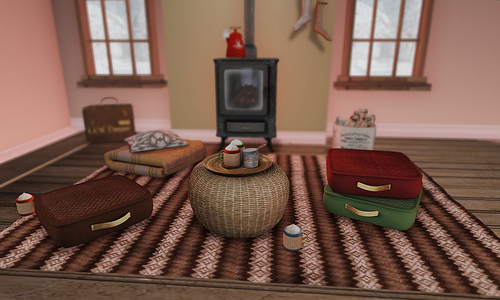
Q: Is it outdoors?
A: Yes, it is outdoors.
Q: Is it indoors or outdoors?
A: It is outdoors.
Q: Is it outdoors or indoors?
A: It is outdoors.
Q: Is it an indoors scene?
A: No, it is outdoors.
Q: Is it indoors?
A: No, it is outdoors.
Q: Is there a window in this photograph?
A: Yes, there is a window.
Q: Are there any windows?
A: Yes, there is a window.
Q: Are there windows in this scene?
A: Yes, there is a window.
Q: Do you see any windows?
A: Yes, there is a window.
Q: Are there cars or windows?
A: Yes, there is a window.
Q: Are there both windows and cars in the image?
A: No, there is a window but no cars.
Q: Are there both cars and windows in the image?
A: No, there is a window but no cars.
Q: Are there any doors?
A: No, there are no doors.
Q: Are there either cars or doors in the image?
A: No, there are no doors or cars.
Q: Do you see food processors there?
A: No, there are no food processors.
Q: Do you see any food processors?
A: No, there are no food processors.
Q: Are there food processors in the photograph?
A: No, there are no food processors.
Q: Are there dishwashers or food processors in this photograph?
A: No, there are no food processors or dishwashers.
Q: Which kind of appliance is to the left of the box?
A: The appliance is a stove.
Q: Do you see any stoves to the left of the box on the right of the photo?
A: Yes, there is a stove to the left of the box.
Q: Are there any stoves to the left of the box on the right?
A: Yes, there is a stove to the left of the box.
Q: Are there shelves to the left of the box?
A: No, there is a stove to the left of the box.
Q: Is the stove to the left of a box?
A: Yes, the stove is to the left of a box.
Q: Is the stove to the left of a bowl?
A: No, the stove is to the left of a box.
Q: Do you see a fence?
A: No, there are no fences.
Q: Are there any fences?
A: No, there are no fences.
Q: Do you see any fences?
A: No, there are no fences.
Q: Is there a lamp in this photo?
A: No, there are no lamps.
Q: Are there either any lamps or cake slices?
A: No, there are no lamps or cake slices.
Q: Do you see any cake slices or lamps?
A: No, there are no lamps or cake slices.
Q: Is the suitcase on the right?
A: No, the suitcase is on the left of the image.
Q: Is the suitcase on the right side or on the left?
A: The suitcase is on the left of the image.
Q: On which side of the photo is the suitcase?
A: The suitcase is on the left of the image.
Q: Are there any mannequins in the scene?
A: No, there are no mannequins.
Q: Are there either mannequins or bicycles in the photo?
A: No, there are no mannequins or bicycles.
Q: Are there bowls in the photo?
A: No, there are no bowls.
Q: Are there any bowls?
A: No, there are no bowls.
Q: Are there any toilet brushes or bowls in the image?
A: No, there are no bowls or toilet brushes.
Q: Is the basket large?
A: Yes, the basket is large.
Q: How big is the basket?
A: The basket is large.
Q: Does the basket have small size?
A: No, the basket is large.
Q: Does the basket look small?
A: No, the basket is large.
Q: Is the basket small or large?
A: The basket is large.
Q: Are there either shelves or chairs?
A: No, there are no chairs or shelves.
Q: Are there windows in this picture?
A: Yes, there is a window.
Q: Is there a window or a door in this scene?
A: Yes, there is a window.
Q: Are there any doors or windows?
A: Yes, there is a window.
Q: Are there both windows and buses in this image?
A: No, there is a window but no buses.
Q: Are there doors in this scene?
A: No, there are no doors.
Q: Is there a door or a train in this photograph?
A: No, there are no doors or trains.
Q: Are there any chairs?
A: No, there are no chairs.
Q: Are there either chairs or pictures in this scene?
A: No, there are no chairs or pictures.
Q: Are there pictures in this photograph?
A: No, there are no pictures.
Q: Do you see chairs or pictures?
A: No, there are no pictures or chairs.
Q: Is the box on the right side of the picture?
A: Yes, the box is on the right of the image.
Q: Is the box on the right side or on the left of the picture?
A: The box is on the right of the image.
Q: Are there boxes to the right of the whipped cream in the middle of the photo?
A: Yes, there is a box to the right of the whipped cream.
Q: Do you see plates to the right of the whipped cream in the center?
A: No, there is a box to the right of the whipped cream.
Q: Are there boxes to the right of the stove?
A: Yes, there is a box to the right of the stove.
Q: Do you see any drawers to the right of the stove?
A: No, there is a box to the right of the stove.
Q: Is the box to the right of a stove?
A: Yes, the box is to the right of a stove.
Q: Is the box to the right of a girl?
A: No, the box is to the right of a stove.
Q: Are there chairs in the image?
A: No, there are no chairs.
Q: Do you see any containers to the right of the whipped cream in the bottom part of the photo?
A: Yes, there is a container to the right of the whipped cream.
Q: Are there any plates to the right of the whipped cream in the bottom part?
A: No, there is a container to the right of the whipped cream.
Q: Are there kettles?
A: Yes, there is a kettle.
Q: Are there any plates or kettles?
A: Yes, there is a kettle.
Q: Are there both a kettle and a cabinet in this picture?
A: No, there is a kettle but no cabinets.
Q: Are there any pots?
A: No, there are no pots.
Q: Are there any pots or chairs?
A: No, there are no pots or chairs.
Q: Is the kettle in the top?
A: Yes, the kettle is in the top of the image.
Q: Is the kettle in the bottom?
A: No, the kettle is in the top of the image.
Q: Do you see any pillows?
A: Yes, there is a pillow.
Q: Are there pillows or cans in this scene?
A: Yes, there is a pillow.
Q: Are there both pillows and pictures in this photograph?
A: No, there is a pillow but no pictures.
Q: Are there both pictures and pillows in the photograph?
A: No, there is a pillow but no pictures.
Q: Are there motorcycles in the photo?
A: No, there are no motorcycles.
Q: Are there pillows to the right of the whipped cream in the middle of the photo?
A: Yes, there is a pillow to the right of the whipped cream.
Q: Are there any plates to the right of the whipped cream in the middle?
A: No, there is a pillow to the right of the whipped cream.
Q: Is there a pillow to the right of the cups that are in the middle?
A: Yes, there is a pillow to the right of the cups.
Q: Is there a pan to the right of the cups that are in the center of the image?
A: No, there is a pillow to the right of the cups.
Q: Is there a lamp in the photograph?
A: No, there are no lamps.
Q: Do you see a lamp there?
A: No, there are no lamps.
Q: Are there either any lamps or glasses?
A: No, there are no lamps or glasses.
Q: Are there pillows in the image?
A: Yes, there is a pillow.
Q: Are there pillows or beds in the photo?
A: Yes, there is a pillow.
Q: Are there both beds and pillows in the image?
A: No, there is a pillow but no beds.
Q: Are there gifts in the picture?
A: No, there are no gifts.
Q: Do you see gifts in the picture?
A: No, there are no gifts.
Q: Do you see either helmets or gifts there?
A: No, there are no gifts or helmets.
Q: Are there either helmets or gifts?
A: No, there are no gifts or helmets.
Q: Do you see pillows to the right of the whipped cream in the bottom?
A: Yes, there is a pillow to the right of the whipped cream.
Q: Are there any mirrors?
A: No, there are no mirrors.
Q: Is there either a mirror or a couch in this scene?
A: No, there are no mirrors or couches.